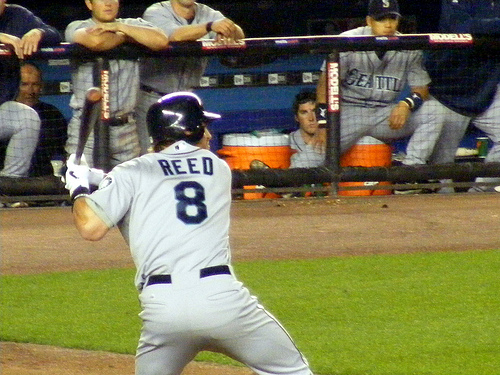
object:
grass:
[0, 247, 499, 374]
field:
[0, 192, 499, 374]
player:
[60, 91, 314, 373]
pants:
[133, 264, 315, 374]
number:
[174, 180, 209, 225]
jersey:
[83, 140, 232, 292]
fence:
[1, 33, 499, 208]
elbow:
[77, 223, 105, 241]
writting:
[157, 156, 213, 176]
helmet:
[145, 91, 221, 144]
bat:
[74, 86, 103, 164]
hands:
[64, 152, 91, 194]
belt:
[144, 264, 232, 287]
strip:
[2, 190, 498, 270]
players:
[64, 0, 169, 174]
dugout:
[0, 0, 499, 207]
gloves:
[64, 152, 93, 200]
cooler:
[215, 132, 297, 200]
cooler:
[336, 136, 391, 197]